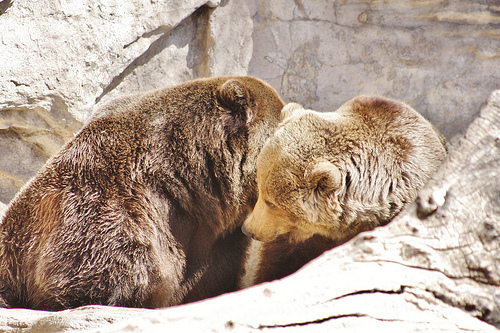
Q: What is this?
A: Bears.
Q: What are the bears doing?
A: Sleeping.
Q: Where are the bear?
A: On a rock.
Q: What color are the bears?
A: Brown.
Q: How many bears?
A: 2.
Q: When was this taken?
A: Daytime.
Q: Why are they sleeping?
A: Tired.